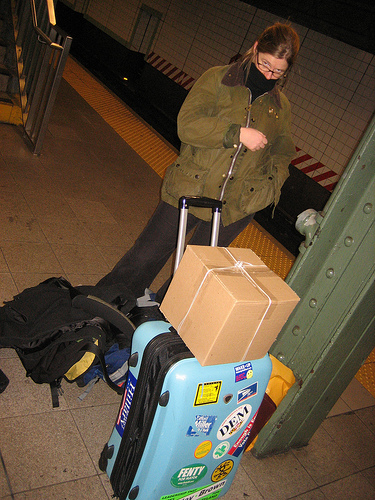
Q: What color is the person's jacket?
A: Brown.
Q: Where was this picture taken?
A: On a train platform.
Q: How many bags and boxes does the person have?
A: Five.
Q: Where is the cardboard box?
A: On top of the blue suitcase.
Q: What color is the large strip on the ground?
A: Yellow.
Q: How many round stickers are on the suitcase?
A: Four.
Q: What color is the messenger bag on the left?
A: Black.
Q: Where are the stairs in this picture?
A: In the upper right corner.